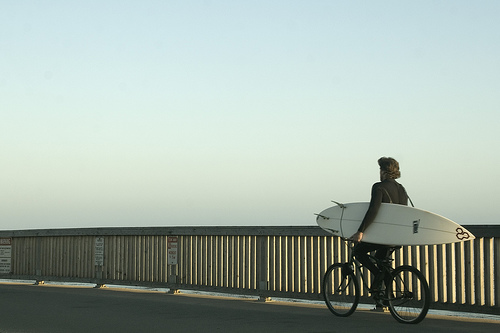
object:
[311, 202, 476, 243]
surfboard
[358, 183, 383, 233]
arm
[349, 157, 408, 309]
man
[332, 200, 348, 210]
fin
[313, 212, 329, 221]
fin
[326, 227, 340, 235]
fin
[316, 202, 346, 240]
tail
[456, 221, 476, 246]
nose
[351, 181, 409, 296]
wetsuit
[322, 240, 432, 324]
bike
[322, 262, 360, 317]
wheel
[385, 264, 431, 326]
wheel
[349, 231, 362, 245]
hand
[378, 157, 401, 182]
hair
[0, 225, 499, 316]
fence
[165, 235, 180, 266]
sign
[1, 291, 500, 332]
street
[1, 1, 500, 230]
sky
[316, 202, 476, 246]
bottom